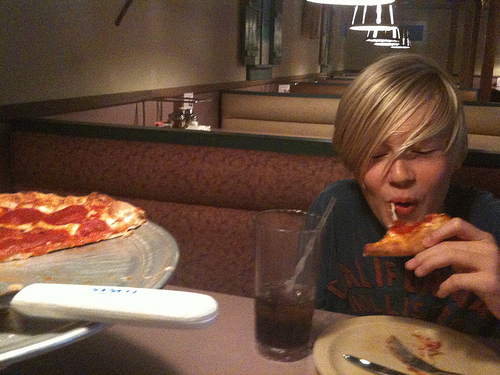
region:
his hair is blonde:
[307, 71, 461, 151]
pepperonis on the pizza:
[7, 190, 114, 239]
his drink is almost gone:
[266, 209, 315, 351]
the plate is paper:
[323, 322, 478, 374]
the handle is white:
[47, 253, 212, 361]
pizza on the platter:
[2, 163, 206, 352]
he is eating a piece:
[377, 185, 449, 265]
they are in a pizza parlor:
[22, 48, 484, 259]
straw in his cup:
[246, 190, 348, 309]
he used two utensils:
[358, 322, 451, 372]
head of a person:
[329, 54, 479, 241]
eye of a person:
[362, 138, 397, 173]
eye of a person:
[408, 140, 450, 162]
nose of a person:
[377, 158, 422, 199]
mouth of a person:
[368, 191, 425, 226]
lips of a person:
[385, 185, 428, 217]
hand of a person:
[399, 211, 493, 312]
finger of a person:
[399, 227, 480, 289]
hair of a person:
[369, 79, 413, 116]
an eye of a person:
[362, 130, 397, 170]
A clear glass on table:
[249, 186, 332, 358]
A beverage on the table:
[248, 190, 333, 363]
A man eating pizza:
[311, 52, 496, 336]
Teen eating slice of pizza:
[303, 57, 495, 322]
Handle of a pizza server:
[18, 281, 223, 323]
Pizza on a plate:
[1, 190, 156, 264]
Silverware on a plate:
[336, 333, 456, 373]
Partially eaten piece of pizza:
[366, 200, 451, 257]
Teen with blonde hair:
[306, 60, 498, 325]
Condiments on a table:
[158, 90, 214, 135]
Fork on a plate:
[381, 328, 476, 373]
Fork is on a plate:
[383, 330, 465, 372]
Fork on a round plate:
[383, 329, 461, 374]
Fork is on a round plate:
[384, 330, 469, 374]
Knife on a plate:
[335, 351, 405, 373]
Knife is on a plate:
[342, 351, 415, 373]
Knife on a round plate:
[337, 348, 405, 373]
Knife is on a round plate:
[342, 346, 412, 373]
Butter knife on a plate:
[340, 347, 411, 374]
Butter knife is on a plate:
[340, 350, 409, 372]